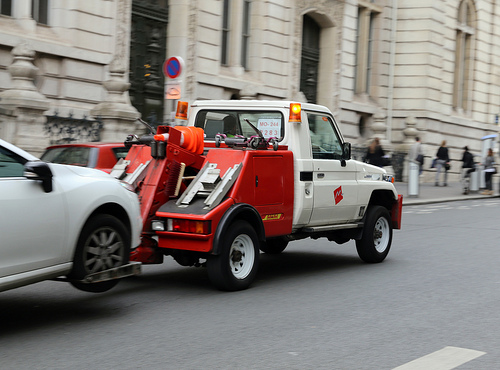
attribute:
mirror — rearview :
[22, 159, 52, 194]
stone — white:
[341, 31, 358, 54]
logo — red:
[333, 184, 343, 203]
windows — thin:
[220, 0, 262, 85]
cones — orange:
[150, 120, 210, 157]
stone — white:
[259, 26, 300, 39]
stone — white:
[399, 32, 438, 41]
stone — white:
[395, 29, 448, 46]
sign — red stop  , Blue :
[160, 53, 190, 85]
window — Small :
[198, 110, 233, 140]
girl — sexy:
[427, 130, 463, 189]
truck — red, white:
[105, 98, 404, 293]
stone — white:
[193, 38, 220, 61]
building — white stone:
[33, 12, 473, 196]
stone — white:
[259, 27, 289, 52]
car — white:
[0, 131, 150, 301]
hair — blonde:
[365, 134, 388, 151]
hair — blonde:
[437, 136, 450, 150]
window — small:
[192, 108, 284, 141]